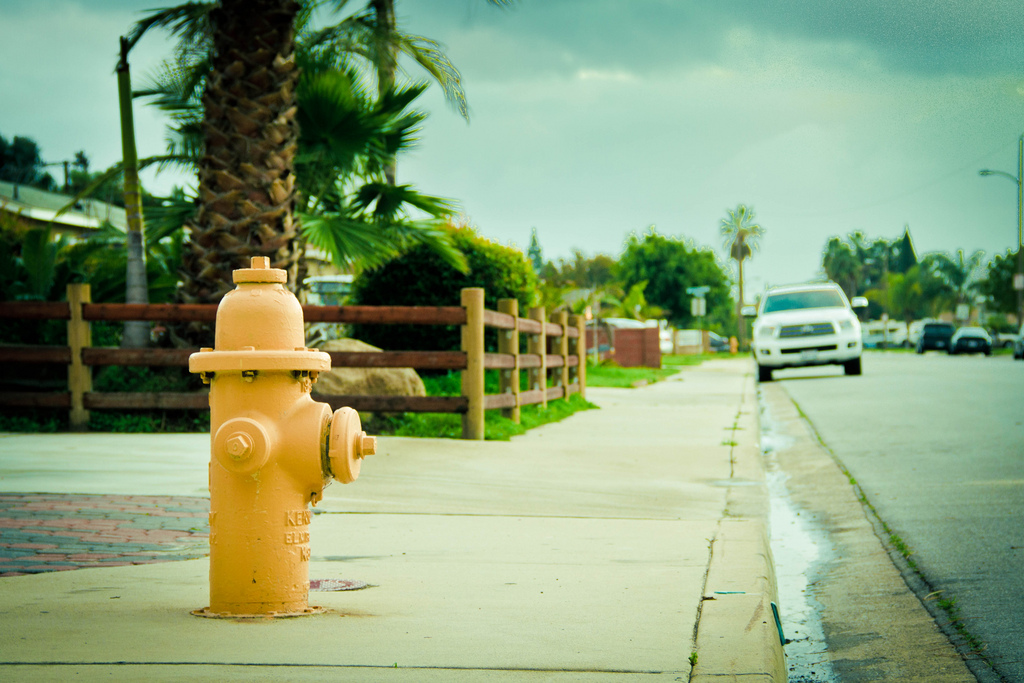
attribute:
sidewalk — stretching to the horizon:
[565, 342, 753, 675]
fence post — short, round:
[47, 273, 130, 448]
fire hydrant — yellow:
[166, 225, 385, 632]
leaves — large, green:
[287, 212, 441, 269]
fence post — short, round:
[443, 270, 504, 459]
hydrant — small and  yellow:
[192, 244, 368, 683]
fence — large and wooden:
[95, 341, 592, 355]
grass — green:
[603, 339, 653, 484]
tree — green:
[639, 218, 737, 331]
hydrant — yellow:
[154, 169, 386, 669]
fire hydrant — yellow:
[185, 242, 386, 618]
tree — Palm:
[600, 221, 976, 345]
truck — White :
[745, 271, 869, 378]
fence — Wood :
[43, 238, 607, 450]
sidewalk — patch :
[388, 359, 756, 668]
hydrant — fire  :
[181, 242, 378, 610]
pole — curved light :
[968, 141, 988, 254]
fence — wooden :
[440, 281, 596, 429]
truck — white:
[756, 275, 867, 386]